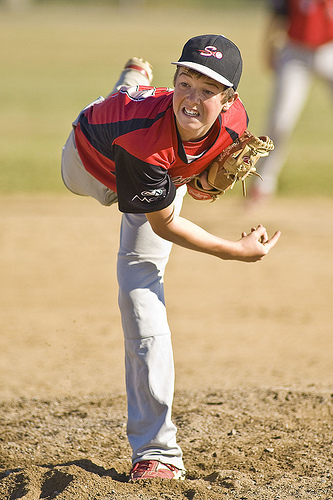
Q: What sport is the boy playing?
A: Baseball.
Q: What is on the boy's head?
A: Baseball cap.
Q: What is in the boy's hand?
A: Baseball mitt.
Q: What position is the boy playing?
A: Pitcher.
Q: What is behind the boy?
A: Another player.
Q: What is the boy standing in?
A: Dirt.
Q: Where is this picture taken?
A: A baseball field.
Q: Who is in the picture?
A: A boy.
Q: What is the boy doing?
A: Playing baseball.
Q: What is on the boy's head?
A: A cap.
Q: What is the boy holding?
A: A mitt.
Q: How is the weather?
A: Sunny.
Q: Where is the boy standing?
A: A mound.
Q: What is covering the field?
A: Grass.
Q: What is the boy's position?
A: Pitcher.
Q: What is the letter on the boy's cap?
A: An S.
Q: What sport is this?
A: Baseball.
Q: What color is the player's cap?
A: Black.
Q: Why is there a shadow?
A: It is sunny.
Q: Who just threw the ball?
A: The pitcher.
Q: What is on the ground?
A: Dirt.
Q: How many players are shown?
A: Two.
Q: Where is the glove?
A: On his hand.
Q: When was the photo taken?
A: Daytime.